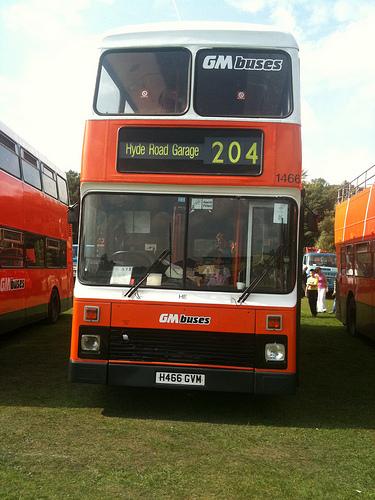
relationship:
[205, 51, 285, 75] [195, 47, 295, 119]
gm buses on right window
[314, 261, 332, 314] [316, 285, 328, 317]
woman wearing skirt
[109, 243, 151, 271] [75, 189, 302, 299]
steering wheel behind windshield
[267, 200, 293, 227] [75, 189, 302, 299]
paper on windshield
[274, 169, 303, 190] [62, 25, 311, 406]
1466 on bus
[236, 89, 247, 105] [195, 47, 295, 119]
sticker on right window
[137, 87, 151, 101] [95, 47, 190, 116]
sticker on left window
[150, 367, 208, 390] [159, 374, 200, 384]
license plate says h466 gvm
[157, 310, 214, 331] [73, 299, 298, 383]
gm buses on bus front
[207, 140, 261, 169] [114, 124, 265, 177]
204 on display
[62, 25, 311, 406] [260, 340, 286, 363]
bus has headlight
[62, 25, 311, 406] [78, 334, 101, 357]
bus has headlight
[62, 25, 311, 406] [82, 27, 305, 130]
bus has second level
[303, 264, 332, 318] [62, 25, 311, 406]
people behind bus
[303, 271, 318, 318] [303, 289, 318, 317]
people wearing pants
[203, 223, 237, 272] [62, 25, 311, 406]
person in bus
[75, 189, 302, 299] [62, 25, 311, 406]
windshield on bus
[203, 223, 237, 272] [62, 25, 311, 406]
person on bus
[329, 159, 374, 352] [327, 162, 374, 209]
bus has open top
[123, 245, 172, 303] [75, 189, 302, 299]
windshield wiper on windshield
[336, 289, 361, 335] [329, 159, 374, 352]
back tire of bus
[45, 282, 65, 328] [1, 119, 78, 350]
back tire of bus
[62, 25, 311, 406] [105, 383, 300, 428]
bus has shadow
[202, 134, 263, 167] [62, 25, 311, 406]
number on bus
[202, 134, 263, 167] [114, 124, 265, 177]
number on display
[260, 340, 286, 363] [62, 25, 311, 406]
headlight on bus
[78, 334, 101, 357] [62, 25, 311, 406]
headlight on bus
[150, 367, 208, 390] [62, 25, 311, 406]
license plate on bus